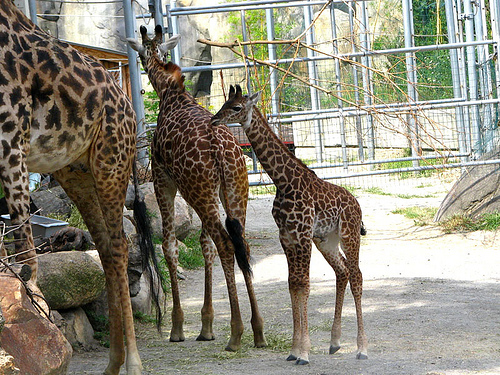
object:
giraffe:
[207, 82, 370, 367]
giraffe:
[123, 20, 273, 355]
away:
[190, 36, 267, 80]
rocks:
[35, 252, 106, 312]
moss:
[43, 271, 106, 304]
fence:
[151, 0, 499, 187]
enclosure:
[13, 2, 500, 201]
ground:
[231, 221, 500, 375]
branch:
[198, 28, 449, 150]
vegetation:
[413, 2, 454, 102]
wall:
[0, 0, 409, 110]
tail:
[215, 148, 260, 279]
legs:
[154, 177, 188, 345]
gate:
[316, 0, 497, 173]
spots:
[295, 213, 304, 223]